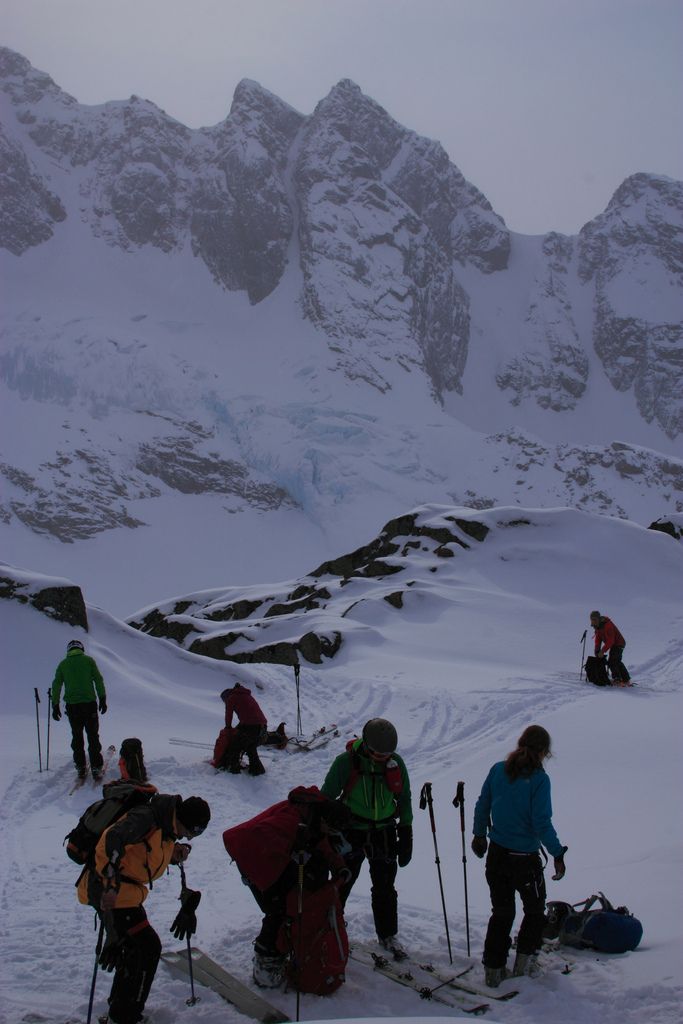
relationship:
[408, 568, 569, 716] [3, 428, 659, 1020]
snow on ground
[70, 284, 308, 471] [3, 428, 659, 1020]
snow on ground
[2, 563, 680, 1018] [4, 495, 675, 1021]
snow on ground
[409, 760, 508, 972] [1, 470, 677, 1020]
poles stuck in snow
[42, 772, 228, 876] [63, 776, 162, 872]
man has a backpack